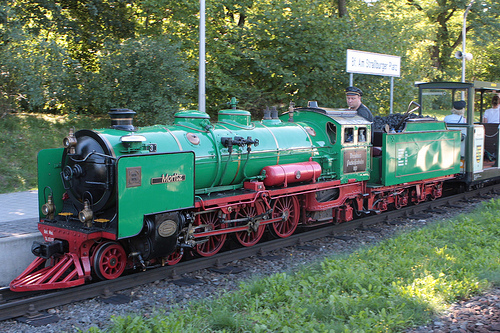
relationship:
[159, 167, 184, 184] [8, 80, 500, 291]
word written on car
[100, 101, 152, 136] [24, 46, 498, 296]
smoke stacks on top of train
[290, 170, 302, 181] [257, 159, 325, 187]
gauge on cylinder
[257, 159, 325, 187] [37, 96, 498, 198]
cylinder on side of train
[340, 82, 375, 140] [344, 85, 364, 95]
man wearing hat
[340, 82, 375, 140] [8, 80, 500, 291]
man driving car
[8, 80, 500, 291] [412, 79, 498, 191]
car has car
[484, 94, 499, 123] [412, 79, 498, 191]
people riding in car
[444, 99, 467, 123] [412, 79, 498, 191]
people riding in car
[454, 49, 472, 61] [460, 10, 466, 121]
speakers on pole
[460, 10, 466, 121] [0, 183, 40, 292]
pole on side of road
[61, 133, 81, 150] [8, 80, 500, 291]
headlight on top of car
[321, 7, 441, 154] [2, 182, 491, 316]
sign on side of tracks